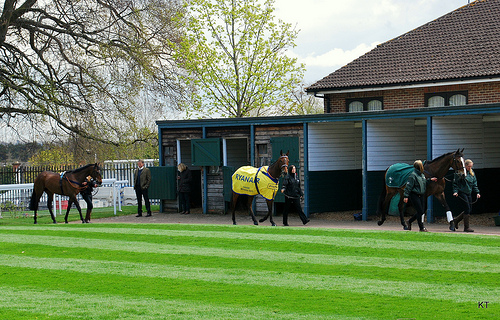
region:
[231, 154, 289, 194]
yellow cover on horse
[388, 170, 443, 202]
green cover on horse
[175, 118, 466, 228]
green dividers for stalls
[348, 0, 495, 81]
brown roof on building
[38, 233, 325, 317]
grass is mowed in stripes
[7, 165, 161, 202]
black fence behind horses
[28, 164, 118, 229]
brown horse near fence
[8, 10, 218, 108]
large and bare tree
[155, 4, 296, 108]
green tree behind stall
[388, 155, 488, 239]
people walking with horse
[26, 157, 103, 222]
brown horse being led by a person and last in line out of the stables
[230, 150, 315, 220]
brown horse with yellow blanket being led by woman in black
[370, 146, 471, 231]
brown horse with teal blanket being lead by men wearing green jackets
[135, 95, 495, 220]
blue and white stables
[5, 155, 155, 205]
black rod iron fence scene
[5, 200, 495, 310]
the lawn runs in front of stables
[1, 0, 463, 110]
the weather is sunny but overcast with clouds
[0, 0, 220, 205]
large tree oaverhanging in foreground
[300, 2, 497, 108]
brick building with tudor style roofing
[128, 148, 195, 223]
two men in suits observing the last horse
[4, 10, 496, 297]
picture taken outdoors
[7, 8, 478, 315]
picture taken during the day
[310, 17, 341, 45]
the sky is full of clouds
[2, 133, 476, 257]
horses are being walked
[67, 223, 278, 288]
the grass is manicured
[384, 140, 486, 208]
wo people walking a horse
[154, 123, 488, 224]
stables behind the horses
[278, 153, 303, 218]
one person walking a horse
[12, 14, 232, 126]
very large tree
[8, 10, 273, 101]
the tree is full of leaves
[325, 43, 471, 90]
a brown tiled roof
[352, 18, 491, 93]
a brown tiled roof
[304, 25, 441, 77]
a brown tiled roof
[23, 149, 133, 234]
the horse is walking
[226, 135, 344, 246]
the horse is walking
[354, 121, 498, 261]
the horse is walking